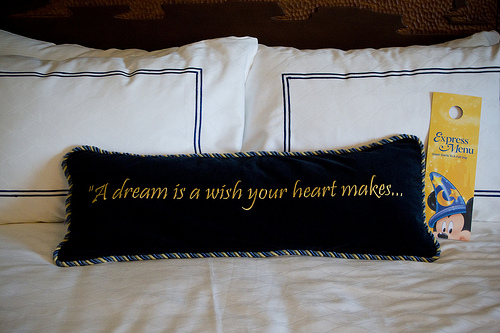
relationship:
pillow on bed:
[236, 29, 499, 222] [1, 26, 499, 331]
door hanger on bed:
[420, 91, 480, 242] [1, 26, 499, 331]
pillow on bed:
[260, 39, 499, 212] [1, 26, 499, 331]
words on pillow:
[86, 183, 413, 199] [236, 29, 499, 222]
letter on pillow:
[93, 181, 112, 207] [236, 29, 499, 222]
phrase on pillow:
[86, 183, 413, 199] [236, 29, 499, 222]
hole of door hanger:
[445, 97, 466, 122] [420, 91, 480, 242]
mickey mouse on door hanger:
[427, 171, 474, 241] [420, 91, 480, 242]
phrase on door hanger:
[434, 120, 478, 167] [420, 91, 480, 242]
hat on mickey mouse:
[426, 174, 465, 212] [427, 171, 474, 241]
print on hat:
[431, 180, 452, 206] [426, 174, 465, 212]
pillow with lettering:
[236, 29, 499, 222] [83, 182, 403, 201]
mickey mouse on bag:
[431, 170, 480, 240] [431, 94, 479, 244]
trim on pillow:
[274, 63, 498, 83] [260, 39, 499, 212]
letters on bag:
[431, 132, 485, 157] [431, 94, 479, 244]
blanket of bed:
[2, 264, 493, 333] [1, 26, 499, 331]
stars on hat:
[433, 173, 439, 185] [426, 174, 465, 212]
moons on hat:
[436, 190, 455, 206] [426, 174, 465, 212]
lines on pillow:
[274, 70, 496, 79] [260, 39, 499, 212]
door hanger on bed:
[420, 91, 475, 236] [1, 26, 499, 331]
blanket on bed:
[0, 219, 500, 333] [1, 26, 499, 331]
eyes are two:
[441, 222, 457, 234] [380, 241, 461, 291]